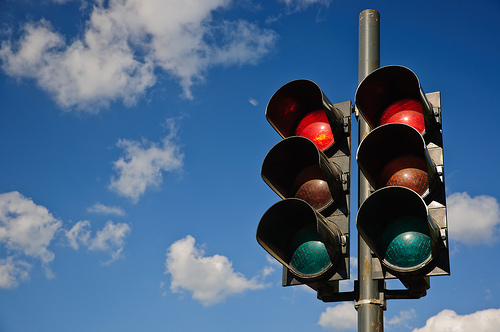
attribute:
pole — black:
[342, 5, 395, 330]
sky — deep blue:
[9, 1, 499, 329]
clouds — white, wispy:
[7, 4, 222, 106]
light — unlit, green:
[280, 226, 336, 282]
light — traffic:
[255, 79, 359, 291]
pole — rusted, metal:
[336, 13, 408, 90]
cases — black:
[279, 148, 401, 249]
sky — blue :
[213, 117, 256, 173]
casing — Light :
[259, 72, 336, 134]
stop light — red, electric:
[253, 76, 353, 288]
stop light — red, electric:
[351, 64, 453, 278]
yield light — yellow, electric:
[358, 122, 440, 195]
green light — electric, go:
[286, 228, 330, 273]